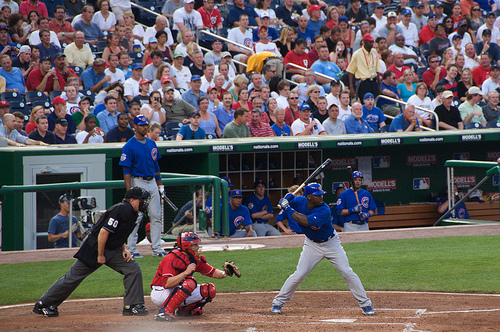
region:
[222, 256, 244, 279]
a brown baseball glove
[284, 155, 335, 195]
a black and brown baseball bat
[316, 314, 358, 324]
a white base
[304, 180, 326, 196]
a blue baseball helmet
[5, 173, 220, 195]
a long green pole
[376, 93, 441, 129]
a silver pole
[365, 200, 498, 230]
part of a wooden bench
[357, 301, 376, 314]
a man's shoe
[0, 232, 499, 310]
a section of green grass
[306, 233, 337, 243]
a man's black belt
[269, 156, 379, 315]
A batter standing at home plate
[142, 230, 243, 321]
A catcher crouching behind home plate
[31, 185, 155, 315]
The umpire leaning over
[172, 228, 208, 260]
A red catcher's helmet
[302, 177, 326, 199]
A shiny blue batter's helmet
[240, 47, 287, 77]
A man in a yellow shirt bending over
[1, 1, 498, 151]
Stands full of baseball spectators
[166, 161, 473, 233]
The team in the baseball dugout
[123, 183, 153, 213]
The umpire's black face guard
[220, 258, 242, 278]
The catcher's leather mitt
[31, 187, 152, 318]
Umpire wearing uniform and mask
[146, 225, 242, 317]
Catcher with mit and red uniform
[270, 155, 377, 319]
Baseball player at bat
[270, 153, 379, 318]
Baseball player wearing blue jersey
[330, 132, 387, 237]
Baseball player in the dugout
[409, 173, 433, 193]
Major League Baseball logo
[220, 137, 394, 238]
Numerous baseball players in dugout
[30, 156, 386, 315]
Baseball player at bat with umpire and catcher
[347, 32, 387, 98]
Man wearing red hat and yellow shirt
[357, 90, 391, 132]
Man wearing baseball hat backwards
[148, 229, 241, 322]
Catcher with glove up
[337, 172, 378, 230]
Chicago Cub standing in the dugout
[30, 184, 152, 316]
Umpire with leg stretched back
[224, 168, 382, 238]
Cubs players in the dugout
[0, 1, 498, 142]
Fans in the stands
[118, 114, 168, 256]
Ball player standing off to side of field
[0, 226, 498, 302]
Green grass on the field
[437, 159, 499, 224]
Railing down to dugout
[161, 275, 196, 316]
Protective shin guard on catcher's lower leg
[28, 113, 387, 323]
players playing baseball in field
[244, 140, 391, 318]
batter ready to hit ball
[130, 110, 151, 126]
baseball hat on a player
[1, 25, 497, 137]
crowd enjoying the game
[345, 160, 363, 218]
baseball bat in player's hands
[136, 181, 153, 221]
guard for the face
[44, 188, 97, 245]
man filming event with camera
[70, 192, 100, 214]
camera used for filming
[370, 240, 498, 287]
grass on ball field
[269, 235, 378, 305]
pants worn by player